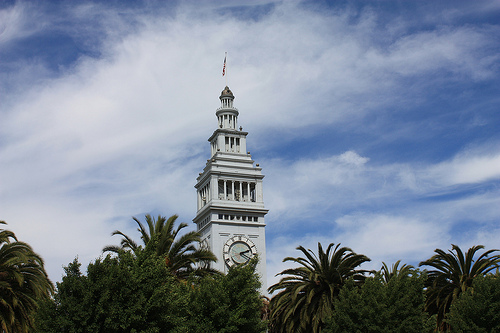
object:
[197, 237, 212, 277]
clock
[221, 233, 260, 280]
clock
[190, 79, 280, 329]
building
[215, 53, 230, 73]
flag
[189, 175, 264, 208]
bell portion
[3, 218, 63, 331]
tree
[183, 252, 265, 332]
tree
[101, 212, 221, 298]
tree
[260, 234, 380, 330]
tree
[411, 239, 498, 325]
tree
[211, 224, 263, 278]
clock face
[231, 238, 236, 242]
numbers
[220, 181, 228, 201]
pillars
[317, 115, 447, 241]
sky